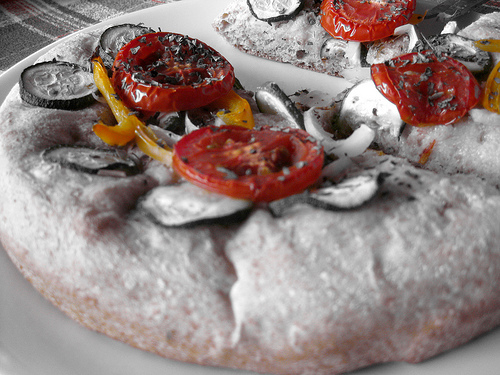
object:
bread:
[0, 0, 500, 375]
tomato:
[371, 50, 481, 128]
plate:
[0, 0, 500, 375]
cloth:
[0, 0, 181, 78]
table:
[0, 0, 500, 76]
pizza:
[0, 0, 500, 375]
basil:
[132, 41, 186, 89]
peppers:
[92, 56, 255, 164]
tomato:
[320, 0, 414, 42]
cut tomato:
[112, 32, 235, 112]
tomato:
[112, 32, 235, 111]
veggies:
[19, 61, 101, 110]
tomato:
[174, 112, 319, 204]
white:
[267, 235, 371, 288]